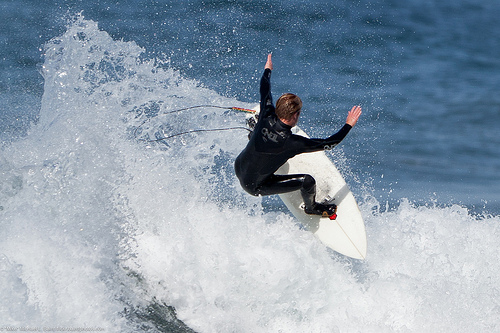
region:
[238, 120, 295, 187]
A black t-shirt in the photo.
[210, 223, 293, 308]
Waves in the photo.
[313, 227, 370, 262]
A surf board in the photo.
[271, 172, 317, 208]
Black pants in the photo.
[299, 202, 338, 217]
Black shoes in the photo.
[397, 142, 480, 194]
Ocean waters in the photo.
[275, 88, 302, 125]
Blonde hair in the photo.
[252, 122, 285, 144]
Writings on the t-shirt.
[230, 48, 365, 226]
A person surfing in the waters.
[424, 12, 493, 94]
Still waters in the ocean.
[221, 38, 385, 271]
surfer in the ocean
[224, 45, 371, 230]
surfer wears black wetsuit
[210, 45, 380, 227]
surfer is bend backwars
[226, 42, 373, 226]
surfer has hands up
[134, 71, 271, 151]
a rope tied the surfboard and the surfer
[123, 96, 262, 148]
rope is color black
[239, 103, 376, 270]
surfboard is white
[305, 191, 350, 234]
red spot on surfboard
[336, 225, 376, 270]
nose of surfboard is pointy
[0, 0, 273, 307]
big splash behind the surfboard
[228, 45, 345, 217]
person is on surfboard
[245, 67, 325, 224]
person has black wetsuit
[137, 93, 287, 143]
black cables near surfer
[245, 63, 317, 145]
arms of man are stretched out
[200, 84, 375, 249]
person makes large waves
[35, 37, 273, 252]
waves are crystal clear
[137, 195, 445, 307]
large white waves near man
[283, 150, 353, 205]
feet are on surfboard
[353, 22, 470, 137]
blue water behind man is wavy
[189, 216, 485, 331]
man is riding heavy waves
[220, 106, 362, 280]
person on white surfboard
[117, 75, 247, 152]
black cables behind surfboard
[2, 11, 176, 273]
white and choppy water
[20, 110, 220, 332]
waves behind person are large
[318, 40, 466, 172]
water is wavy behind surfer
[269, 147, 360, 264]
feet on white surfboard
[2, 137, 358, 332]
person is riding on heavy surf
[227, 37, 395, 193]
arms are stretched out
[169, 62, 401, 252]
person is on surfboard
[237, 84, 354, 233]
person wears white wetsuit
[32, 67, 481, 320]
tall and white waves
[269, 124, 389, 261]
person on white surfboard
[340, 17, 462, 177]
calm water behind person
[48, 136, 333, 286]
large waves near person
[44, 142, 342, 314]
white waves are crashing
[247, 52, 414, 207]
person has arms extended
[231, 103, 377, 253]
feet are on surfboard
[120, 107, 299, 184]
black cables extended from surfboard